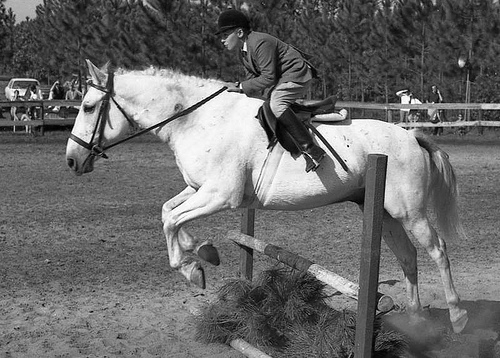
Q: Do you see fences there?
A: Yes, there is a fence.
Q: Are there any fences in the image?
A: Yes, there is a fence.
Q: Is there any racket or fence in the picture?
A: Yes, there is a fence.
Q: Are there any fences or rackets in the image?
A: Yes, there is a fence.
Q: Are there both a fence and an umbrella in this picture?
A: No, there is a fence but no umbrellas.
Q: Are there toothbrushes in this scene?
A: No, there are no toothbrushes.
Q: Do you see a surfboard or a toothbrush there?
A: No, there are no toothbrushes or surfboards.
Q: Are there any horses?
A: Yes, there is a horse.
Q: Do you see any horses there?
A: Yes, there is a horse.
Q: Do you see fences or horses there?
A: Yes, there is a horse.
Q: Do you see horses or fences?
A: Yes, there is a horse.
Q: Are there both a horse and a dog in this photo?
A: No, there is a horse but no dogs.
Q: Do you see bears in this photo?
A: No, there are no bears.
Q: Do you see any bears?
A: No, there are no bears.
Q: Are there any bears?
A: No, there are no bears.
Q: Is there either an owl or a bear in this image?
A: No, there are no bears or owls.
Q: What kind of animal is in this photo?
A: The animal is a horse.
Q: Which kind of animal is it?
A: The animal is a horse.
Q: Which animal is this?
A: That is a horse.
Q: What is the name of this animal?
A: That is a horse.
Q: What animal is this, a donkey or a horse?
A: That is a horse.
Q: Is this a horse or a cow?
A: This is a horse.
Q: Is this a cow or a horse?
A: This is a horse.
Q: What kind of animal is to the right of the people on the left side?
A: The animal is a horse.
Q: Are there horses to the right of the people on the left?
A: Yes, there is a horse to the right of the people.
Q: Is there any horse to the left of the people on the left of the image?
A: No, the horse is to the right of the people.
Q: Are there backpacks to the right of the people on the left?
A: No, there is a horse to the right of the people.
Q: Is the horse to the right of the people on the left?
A: Yes, the horse is to the right of the people.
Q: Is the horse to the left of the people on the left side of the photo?
A: No, the horse is to the right of the people.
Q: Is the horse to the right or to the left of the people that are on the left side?
A: The horse is to the right of the people.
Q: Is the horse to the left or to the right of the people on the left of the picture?
A: The horse is to the right of the people.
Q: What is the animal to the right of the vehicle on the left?
A: The animal is a horse.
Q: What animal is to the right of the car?
A: The animal is a horse.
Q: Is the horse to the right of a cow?
A: No, the horse is to the right of a car.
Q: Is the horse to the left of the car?
A: No, the horse is to the right of the car.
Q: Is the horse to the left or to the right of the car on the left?
A: The horse is to the right of the car.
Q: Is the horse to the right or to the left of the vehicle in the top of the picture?
A: The horse is to the right of the car.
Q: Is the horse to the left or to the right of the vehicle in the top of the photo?
A: The horse is to the right of the car.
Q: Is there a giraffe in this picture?
A: No, there are no giraffes.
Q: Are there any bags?
A: No, there are no bags.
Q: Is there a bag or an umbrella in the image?
A: No, there are no bags or umbrellas.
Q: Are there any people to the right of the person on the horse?
A: Yes, there are people to the right of the girl.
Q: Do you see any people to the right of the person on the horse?
A: Yes, there are people to the right of the girl.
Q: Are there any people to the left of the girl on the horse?
A: No, the people are to the right of the girl.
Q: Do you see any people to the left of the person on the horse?
A: No, the people are to the right of the girl.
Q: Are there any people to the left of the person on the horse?
A: No, the people are to the right of the girl.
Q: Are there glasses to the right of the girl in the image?
A: No, there are people to the right of the girl.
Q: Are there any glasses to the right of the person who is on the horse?
A: No, there are people to the right of the girl.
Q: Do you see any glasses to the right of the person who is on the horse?
A: No, there are people to the right of the girl.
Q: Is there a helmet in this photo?
A: Yes, there is a helmet.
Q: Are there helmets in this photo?
A: Yes, there is a helmet.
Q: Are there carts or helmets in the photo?
A: Yes, there is a helmet.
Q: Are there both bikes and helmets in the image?
A: No, there is a helmet but no bikes.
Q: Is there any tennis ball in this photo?
A: No, there are no tennis balls.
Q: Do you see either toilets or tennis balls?
A: No, there are no tennis balls or toilets.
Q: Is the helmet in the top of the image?
A: Yes, the helmet is in the top of the image.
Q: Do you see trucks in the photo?
A: No, there are no trucks.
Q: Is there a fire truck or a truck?
A: No, there are no trucks or fire trucks.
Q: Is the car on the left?
A: Yes, the car is on the left of the image.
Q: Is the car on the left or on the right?
A: The car is on the left of the image.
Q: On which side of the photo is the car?
A: The car is on the left of the image.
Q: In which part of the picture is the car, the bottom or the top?
A: The car is in the top of the image.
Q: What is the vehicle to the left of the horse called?
A: The vehicle is a car.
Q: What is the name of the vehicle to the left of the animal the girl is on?
A: The vehicle is a car.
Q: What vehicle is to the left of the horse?
A: The vehicle is a car.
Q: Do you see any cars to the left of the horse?
A: Yes, there is a car to the left of the horse.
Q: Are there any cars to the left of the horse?
A: Yes, there is a car to the left of the horse.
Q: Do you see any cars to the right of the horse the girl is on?
A: No, the car is to the left of the horse.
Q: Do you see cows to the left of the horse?
A: No, there is a car to the left of the horse.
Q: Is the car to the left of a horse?
A: Yes, the car is to the left of a horse.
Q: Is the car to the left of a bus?
A: No, the car is to the left of a horse.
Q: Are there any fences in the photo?
A: Yes, there is a fence.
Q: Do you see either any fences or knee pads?
A: Yes, there is a fence.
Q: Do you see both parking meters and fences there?
A: No, there is a fence but no parking meters.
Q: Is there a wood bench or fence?
A: Yes, there is a wood fence.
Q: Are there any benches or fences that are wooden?
A: Yes, the fence is wooden.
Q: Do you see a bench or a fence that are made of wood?
A: Yes, the fence is made of wood.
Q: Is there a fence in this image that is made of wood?
A: Yes, there is a fence that is made of wood.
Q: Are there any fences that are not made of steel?
A: Yes, there is a fence that is made of wood.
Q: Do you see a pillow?
A: No, there are no pillows.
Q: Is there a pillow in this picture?
A: No, there are no pillows.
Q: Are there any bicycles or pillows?
A: No, there are no pillows or bicycles.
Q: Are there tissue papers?
A: No, there are no tissue papers.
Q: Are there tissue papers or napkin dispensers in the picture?
A: No, there are no tissue papers or napkin dispensers.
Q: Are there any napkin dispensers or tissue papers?
A: No, there are no tissue papers or napkin dispensers.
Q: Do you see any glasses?
A: No, there are no glasses.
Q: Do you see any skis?
A: No, there are no skis.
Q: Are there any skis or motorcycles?
A: No, there are no skis or motorcycles.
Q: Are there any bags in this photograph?
A: No, there are no bags.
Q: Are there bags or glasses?
A: No, there are no bags or glasses.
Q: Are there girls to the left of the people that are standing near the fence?
A: Yes, there is a girl to the left of the people.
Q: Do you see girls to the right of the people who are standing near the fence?
A: No, the girl is to the left of the people.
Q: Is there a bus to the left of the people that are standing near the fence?
A: No, there is a girl to the left of the people.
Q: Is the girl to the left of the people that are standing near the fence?
A: Yes, the girl is to the left of the people.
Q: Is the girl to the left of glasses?
A: No, the girl is to the left of the people.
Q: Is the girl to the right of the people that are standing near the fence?
A: No, the girl is to the left of the people.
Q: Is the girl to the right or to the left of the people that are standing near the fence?
A: The girl is to the left of the people.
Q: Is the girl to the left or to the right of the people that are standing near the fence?
A: The girl is to the left of the people.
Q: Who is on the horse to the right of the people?
A: The girl is on the horse.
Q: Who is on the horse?
A: The girl is on the horse.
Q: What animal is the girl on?
A: The girl is on the horse.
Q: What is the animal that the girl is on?
A: The animal is a horse.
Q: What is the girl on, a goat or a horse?
A: The girl is on a horse.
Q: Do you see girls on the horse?
A: Yes, there is a girl on the horse.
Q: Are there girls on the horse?
A: Yes, there is a girl on the horse.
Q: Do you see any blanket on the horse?
A: No, there is a girl on the horse.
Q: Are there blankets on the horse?
A: No, there is a girl on the horse.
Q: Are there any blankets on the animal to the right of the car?
A: No, there is a girl on the horse.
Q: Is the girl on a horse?
A: Yes, the girl is on a horse.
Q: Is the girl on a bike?
A: No, the girl is on a horse.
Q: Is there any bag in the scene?
A: No, there are no bags.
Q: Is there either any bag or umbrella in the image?
A: No, there are no bags or umbrellas.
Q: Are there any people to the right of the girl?
A: Yes, there are people to the right of the girl.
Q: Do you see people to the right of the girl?
A: Yes, there are people to the right of the girl.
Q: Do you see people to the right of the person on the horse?
A: Yes, there are people to the right of the girl.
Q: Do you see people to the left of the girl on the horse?
A: No, the people are to the right of the girl.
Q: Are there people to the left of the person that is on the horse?
A: No, the people are to the right of the girl.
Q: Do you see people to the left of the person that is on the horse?
A: No, the people are to the right of the girl.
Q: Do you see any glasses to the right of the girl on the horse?
A: No, there are people to the right of the girl.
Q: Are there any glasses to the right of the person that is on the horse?
A: No, there are people to the right of the girl.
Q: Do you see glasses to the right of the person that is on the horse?
A: No, there are people to the right of the girl.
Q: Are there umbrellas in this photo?
A: No, there are no umbrellas.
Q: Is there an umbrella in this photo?
A: No, there are no umbrellas.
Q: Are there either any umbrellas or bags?
A: No, there are no umbrellas or bags.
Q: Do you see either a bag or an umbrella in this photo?
A: No, there are no umbrellas or bags.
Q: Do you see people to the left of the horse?
A: Yes, there are people to the left of the horse.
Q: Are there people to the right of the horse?
A: No, the people are to the left of the horse.